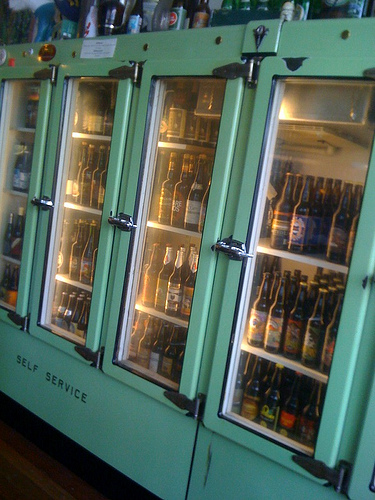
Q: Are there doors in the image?
A: Yes, there is a door.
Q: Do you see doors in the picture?
A: Yes, there is a door.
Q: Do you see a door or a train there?
A: Yes, there is a door.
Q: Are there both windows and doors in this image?
A: Yes, there are both a door and a window.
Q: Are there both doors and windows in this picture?
A: Yes, there are both a door and a window.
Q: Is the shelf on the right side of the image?
A: Yes, the shelf is on the right of the image.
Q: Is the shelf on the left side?
A: No, the shelf is on the right of the image.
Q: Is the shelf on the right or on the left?
A: The shelf is on the right of the image.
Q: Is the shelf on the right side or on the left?
A: The shelf is on the right of the image.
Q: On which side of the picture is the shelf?
A: The shelf is on the right of the image.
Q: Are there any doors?
A: Yes, there is a door.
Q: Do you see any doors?
A: Yes, there is a door.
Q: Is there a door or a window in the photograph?
A: Yes, there is a door.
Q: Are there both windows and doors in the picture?
A: Yes, there are both a door and windows.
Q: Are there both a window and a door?
A: Yes, there are both a door and a window.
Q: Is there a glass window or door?
A: Yes, there is a glass door.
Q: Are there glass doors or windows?
A: Yes, there is a glass door.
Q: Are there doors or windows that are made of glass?
A: Yes, the door is made of glass.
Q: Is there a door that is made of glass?
A: Yes, there is a door that is made of glass.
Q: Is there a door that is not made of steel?
A: Yes, there is a door that is made of glass.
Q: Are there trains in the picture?
A: No, there are no trains.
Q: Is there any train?
A: No, there are no trains.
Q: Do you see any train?
A: No, there are no trains.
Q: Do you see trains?
A: No, there are no trains.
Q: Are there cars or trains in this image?
A: No, there are no trains or cars.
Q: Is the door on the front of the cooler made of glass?
A: Yes, the door is made of glass.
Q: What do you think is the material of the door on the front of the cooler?
A: The door is made of glass.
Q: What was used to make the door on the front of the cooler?
A: The door is made of glass.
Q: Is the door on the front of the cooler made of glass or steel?
A: The door is made of glass.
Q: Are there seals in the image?
A: Yes, there is a seal.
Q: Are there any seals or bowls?
A: Yes, there is a seal.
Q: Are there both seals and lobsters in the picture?
A: No, there is a seal but no lobsters.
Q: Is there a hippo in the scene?
A: No, there are no hippoes.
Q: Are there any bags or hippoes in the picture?
A: No, there are no hippoes or bags.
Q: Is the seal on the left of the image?
A: Yes, the seal is on the left of the image.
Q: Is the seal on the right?
A: No, the seal is on the left of the image.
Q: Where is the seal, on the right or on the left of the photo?
A: The seal is on the left of the image.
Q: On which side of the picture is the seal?
A: The seal is on the left of the image.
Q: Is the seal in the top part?
A: Yes, the seal is in the top of the image.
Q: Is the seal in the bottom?
A: No, the seal is in the top of the image.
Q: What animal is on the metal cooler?
A: The animal is a seal.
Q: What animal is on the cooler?
A: The animal is a seal.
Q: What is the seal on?
A: The seal is on the cooler.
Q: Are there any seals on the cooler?
A: Yes, there is a seal on the cooler.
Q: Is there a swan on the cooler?
A: No, there is a seal on the cooler.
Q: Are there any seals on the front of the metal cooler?
A: Yes, there is a seal on the front of the cooler.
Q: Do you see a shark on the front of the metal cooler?
A: No, there is a seal on the front of the cooler.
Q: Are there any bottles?
A: Yes, there is a bottle.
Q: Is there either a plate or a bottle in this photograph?
A: Yes, there is a bottle.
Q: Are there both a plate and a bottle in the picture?
A: No, there is a bottle but no plates.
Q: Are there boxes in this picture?
A: No, there are no boxes.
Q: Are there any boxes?
A: No, there are no boxes.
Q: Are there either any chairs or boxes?
A: No, there are no boxes or chairs.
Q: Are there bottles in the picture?
A: Yes, there is a bottle.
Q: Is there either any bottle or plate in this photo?
A: Yes, there is a bottle.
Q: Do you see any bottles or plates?
A: Yes, there is a bottle.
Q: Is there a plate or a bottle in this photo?
A: Yes, there is a bottle.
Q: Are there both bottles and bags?
A: No, there is a bottle but no bags.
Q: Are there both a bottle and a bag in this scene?
A: No, there is a bottle but no bags.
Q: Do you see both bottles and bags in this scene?
A: No, there is a bottle but no bags.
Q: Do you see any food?
A: No, there is no food.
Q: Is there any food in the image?
A: No, there is no food.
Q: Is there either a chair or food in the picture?
A: No, there are no food or chairs.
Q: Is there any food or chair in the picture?
A: No, there are no food or chairs.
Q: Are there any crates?
A: No, there are no crates.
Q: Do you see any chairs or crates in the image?
A: No, there are no crates or chairs.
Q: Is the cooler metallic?
A: Yes, the cooler is metallic.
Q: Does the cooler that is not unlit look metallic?
A: Yes, the cooler is metallic.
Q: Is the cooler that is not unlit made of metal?
A: Yes, the cooler is made of metal.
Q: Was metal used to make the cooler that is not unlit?
A: Yes, the cooler is made of metal.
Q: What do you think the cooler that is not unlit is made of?
A: The cooler is made of metal.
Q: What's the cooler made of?
A: The cooler is made of metal.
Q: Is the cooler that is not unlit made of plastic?
A: No, the cooler is made of metal.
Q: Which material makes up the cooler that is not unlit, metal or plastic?
A: The cooler is made of metal.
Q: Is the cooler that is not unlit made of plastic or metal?
A: The cooler is made of metal.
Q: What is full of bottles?
A: The cooler is full of bottles.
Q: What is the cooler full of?
A: The cooler is full of bottles.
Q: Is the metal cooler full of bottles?
A: Yes, the cooler is full of bottles.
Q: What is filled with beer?
A: The cooler is filled with beer.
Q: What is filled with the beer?
A: The cooler is filled with beer.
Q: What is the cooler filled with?
A: The cooler is filled with beer.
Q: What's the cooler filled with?
A: The cooler is filled with beer.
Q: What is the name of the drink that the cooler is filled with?
A: The drink is beer.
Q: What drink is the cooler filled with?
A: The cooler is filled with beer.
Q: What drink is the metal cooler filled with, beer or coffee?
A: The cooler is filled with beer.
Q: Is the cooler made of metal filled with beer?
A: Yes, the cooler is filled with beer.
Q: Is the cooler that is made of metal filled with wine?
A: No, the cooler is filled with beer.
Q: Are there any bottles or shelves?
A: Yes, there is a bottle.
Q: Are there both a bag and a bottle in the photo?
A: No, there is a bottle but no bags.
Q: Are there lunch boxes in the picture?
A: No, there are no lunch boxes.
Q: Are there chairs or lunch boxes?
A: No, there are no lunch boxes or chairs.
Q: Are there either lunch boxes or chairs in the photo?
A: No, there are no lunch boxes or chairs.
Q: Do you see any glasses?
A: No, there are no glasses.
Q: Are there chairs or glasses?
A: No, there are no glasses or chairs.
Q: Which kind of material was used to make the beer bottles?
A: The bottles are made of glass.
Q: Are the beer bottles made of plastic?
A: No, the bottles are made of glass.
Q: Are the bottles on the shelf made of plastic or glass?
A: The bottles are made of glass.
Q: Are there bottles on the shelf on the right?
A: Yes, there are bottles on the shelf.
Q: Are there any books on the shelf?
A: No, there are bottles on the shelf.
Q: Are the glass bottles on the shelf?
A: Yes, the bottles are on the shelf.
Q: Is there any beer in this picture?
A: Yes, there is beer.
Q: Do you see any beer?
A: Yes, there is beer.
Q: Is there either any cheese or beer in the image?
A: Yes, there is beer.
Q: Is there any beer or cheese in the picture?
A: Yes, there is beer.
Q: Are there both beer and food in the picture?
A: No, there is beer but no food.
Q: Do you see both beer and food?
A: No, there is beer but no food.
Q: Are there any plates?
A: No, there are no plates.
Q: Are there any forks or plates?
A: No, there are no plates or forks.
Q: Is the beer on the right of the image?
A: Yes, the beer is on the right of the image.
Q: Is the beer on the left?
A: No, the beer is on the right of the image.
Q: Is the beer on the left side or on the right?
A: The beer is on the right of the image.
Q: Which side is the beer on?
A: The beer is on the right of the image.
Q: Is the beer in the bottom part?
A: Yes, the beer is in the bottom of the image.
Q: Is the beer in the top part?
A: No, the beer is in the bottom of the image.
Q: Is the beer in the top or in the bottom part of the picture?
A: The beer is in the bottom of the image.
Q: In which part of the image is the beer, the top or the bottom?
A: The beer is in the bottom of the image.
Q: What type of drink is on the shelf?
A: The drink is beer.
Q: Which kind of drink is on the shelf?
A: The drink is beer.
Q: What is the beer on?
A: The beer is on the shelf.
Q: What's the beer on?
A: The beer is on the shelf.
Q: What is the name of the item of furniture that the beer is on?
A: The piece of furniture is a shelf.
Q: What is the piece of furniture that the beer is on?
A: The piece of furniture is a shelf.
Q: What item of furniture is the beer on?
A: The beer is on the shelf.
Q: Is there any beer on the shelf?
A: Yes, there is beer on the shelf.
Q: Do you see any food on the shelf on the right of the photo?
A: No, there is beer on the shelf.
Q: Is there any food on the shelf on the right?
A: No, there is beer on the shelf.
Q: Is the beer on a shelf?
A: Yes, the beer is on a shelf.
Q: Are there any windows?
A: Yes, there is a window.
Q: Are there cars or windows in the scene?
A: Yes, there is a window.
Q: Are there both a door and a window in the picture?
A: Yes, there are both a window and a door.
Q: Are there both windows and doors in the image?
A: Yes, there are both a window and a door.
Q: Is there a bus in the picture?
A: No, there are no buses.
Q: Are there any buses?
A: No, there are no buses.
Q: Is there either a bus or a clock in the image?
A: No, there are no buses or clocks.